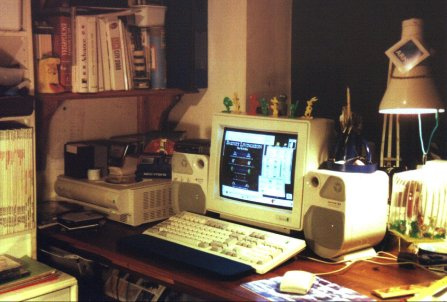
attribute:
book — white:
[105, 17, 128, 88]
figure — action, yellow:
[228, 90, 245, 119]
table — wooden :
[42, 162, 444, 300]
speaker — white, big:
[296, 161, 393, 272]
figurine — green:
[259, 97, 269, 116]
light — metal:
[364, 54, 429, 140]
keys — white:
[155, 211, 289, 265]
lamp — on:
[378, 17, 445, 166]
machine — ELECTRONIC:
[53, 162, 172, 223]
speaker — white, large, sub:
[163, 140, 219, 224]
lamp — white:
[378, 16, 446, 123]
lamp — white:
[378, 15, 444, 114]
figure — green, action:
[220, 84, 234, 114]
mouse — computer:
[280, 261, 324, 298]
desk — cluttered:
[64, 197, 436, 300]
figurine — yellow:
[303, 96, 317, 120]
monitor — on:
[204, 109, 336, 232]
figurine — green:
[283, 97, 300, 121]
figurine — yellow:
[230, 90, 241, 112]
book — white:
[75, 14, 89, 97]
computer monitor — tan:
[205, 112, 340, 234]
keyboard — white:
[154, 208, 298, 269]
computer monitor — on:
[202, 101, 338, 234]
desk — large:
[43, 160, 445, 299]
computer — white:
[204, 106, 335, 237]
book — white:
[80, 18, 106, 90]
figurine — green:
[222, 93, 233, 114]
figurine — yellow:
[268, 97, 279, 115]